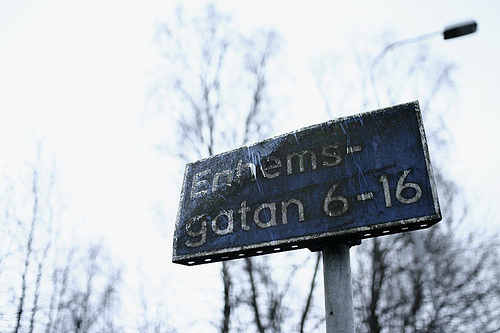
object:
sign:
[172, 99, 442, 266]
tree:
[145, 5, 282, 331]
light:
[442, 19, 479, 41]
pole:
[323, 243, 355, 332]